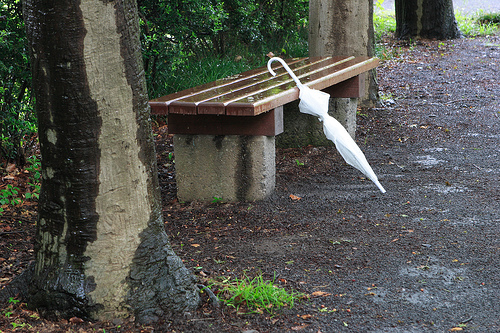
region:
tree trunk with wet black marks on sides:
[3, 5, 203, 327]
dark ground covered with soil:
[170, 8, 492, 328]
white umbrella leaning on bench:
[146, 45, 388, 206]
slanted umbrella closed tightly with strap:
[267, 50, 387, 197]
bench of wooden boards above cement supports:
[146, 53, 376, 208]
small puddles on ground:
[385, 125, 478, 315]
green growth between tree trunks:
[37, 4, 375, 179]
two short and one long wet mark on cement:
[171, 126, 276, 207]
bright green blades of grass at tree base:
[143, 247, 296, 314]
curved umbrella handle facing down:
[262, 47, 316, 113]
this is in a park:
[22, 31, 489, 284]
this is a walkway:
[406, 92, 497, 301]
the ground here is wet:
[380, 154, 465, 329]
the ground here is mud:
[393, 173, 437, 311]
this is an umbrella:
[266, 64, 398, 187]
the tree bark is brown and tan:
[52, 32, 214, 286]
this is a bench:
[168, 83, 281, 158]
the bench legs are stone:
[178, 134, 279, 191]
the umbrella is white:
[329, 76, 388, 203]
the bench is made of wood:
[178, 79, 290, 142]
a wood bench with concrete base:
[153, 49, 378, 192]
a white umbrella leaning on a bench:
[260, 40, 397, 195]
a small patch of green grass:
[221, 274, 296, 316]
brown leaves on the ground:
[403, 33, 468, 93]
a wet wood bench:
[153, 48, 371, 136]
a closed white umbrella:
[274, 31, 370, 190]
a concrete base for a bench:
[172, 115, 288, 222]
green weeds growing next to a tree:
[0, 143, 45, 218]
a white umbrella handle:
[253, 47, 303, 82]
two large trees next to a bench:
[41, 17, 383, 222]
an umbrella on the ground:
[204, 34, 485, 268]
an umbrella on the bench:
[243, 42, 415, 305]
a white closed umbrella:
[247, 49, 401, 195]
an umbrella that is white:
[244, 42, 433, 229]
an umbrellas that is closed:
[257, 56, 371, 174]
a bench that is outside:
[164, 32, 402, 149]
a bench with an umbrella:
[154, 36, 468, 208]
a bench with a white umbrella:
[167, 43, 492, 245]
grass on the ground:
[201, 239, 335, 314]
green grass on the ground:
[191, 243, 318, 331]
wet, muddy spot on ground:
[396, 261, 469, 303]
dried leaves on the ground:
[279, 312, 318, 329]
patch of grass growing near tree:
[218, 271, 303, 306]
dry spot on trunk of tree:
[106, 178, 145, 219]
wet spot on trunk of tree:
[32, 171, 89, 296]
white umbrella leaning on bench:
[264, 51, 385, 193]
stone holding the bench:
[171, 135, 275, 202]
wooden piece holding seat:
[166, 116, 285, 137]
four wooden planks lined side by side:
[155, 95, 265, 117]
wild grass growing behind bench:
[199, 55, 229, 65]